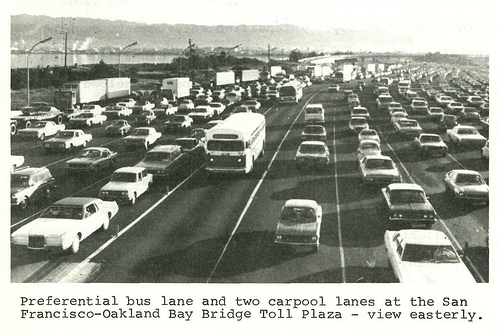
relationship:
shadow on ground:
[134, 231, 272, 275] [179, 188, 268, 223]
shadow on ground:
[271, 178, 372, 202] [179, 188, 268, 223]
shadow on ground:
[319, 203, 382, 247] [179, 188, 268, 223]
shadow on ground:
[255, 159, 294, 177] [179, 188, 268, 223]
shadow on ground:
[385, 141, 418, 166] [179, 188, 268, 223]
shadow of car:
[134, 231, 272, 275] [271, 199, 323, 249]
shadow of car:
[255, 159, 294, 177] [295, 140, 330, 168]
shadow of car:
[271, 178, 372, 202] [356, 154, 399, 182]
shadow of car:
[385, 141, 418, 166] [413, 131, 447, 158]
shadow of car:
[319, 203, 382, 247] [380, 181, 435, 223]